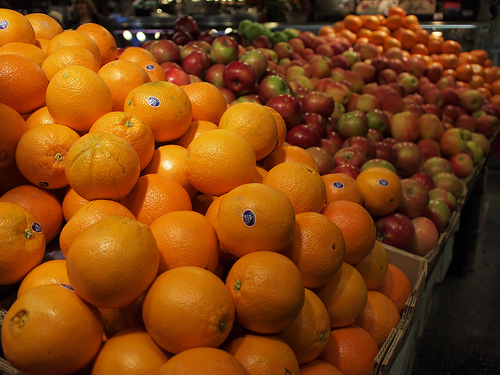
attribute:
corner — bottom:
[0, 293, 110, 373]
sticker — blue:
[243, 207, 255, 227]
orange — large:
[218, 186, 293, 255]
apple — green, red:
[339, 110, 369, 138]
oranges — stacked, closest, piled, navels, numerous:
[2, 7, 407, 375]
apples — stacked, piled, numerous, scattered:
[141, 24, 472, 251]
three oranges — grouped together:
[66, 215, 238, 349]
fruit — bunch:
[5, 3, 496, 360]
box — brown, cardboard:
[373, 254, 433, 368]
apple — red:
[290, 123, 321, 151]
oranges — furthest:
[340, 1, 498, 101]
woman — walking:
[71, 1, 101, 26]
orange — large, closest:
[2, 289, 105, 373]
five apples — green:
[239, 18, 297, 43]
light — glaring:
[430, 20, 447, 40]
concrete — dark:
[418, 163, 497, 373]